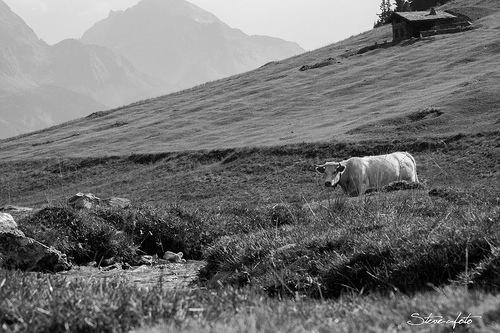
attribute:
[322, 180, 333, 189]
muzzle — squared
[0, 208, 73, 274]
rock — beside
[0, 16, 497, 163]
slope — grassy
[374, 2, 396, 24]
trees — beside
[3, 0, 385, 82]
sky — faded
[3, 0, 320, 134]
mountains — faded, distant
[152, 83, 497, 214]
hill — grassy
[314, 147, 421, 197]
cow — beneath, standing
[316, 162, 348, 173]
ears — perpendicular, darker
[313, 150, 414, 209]
cow — light, tan, blonde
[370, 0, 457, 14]
trees — distant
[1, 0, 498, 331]
picture — white, black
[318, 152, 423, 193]
cow — standing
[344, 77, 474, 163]
pit — small